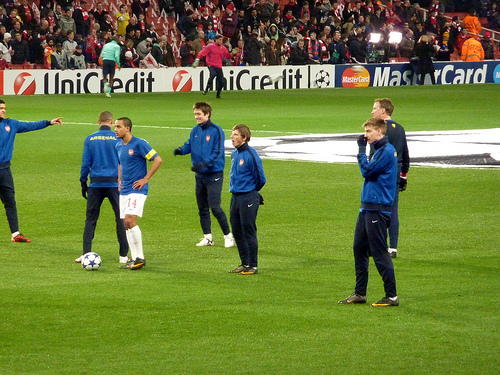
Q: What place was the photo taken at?
A: It was taken at the field.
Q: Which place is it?
A: It is a field.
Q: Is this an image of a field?
A: Yes, it is showing a field.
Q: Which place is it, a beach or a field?
A: It is a field.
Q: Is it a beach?
A: No, it is a field.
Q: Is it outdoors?
A: Yes, it is outdoors.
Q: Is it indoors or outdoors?
A: It is outdoors.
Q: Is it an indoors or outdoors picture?
A: It is outdoors.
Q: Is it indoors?
A: No, it is outdoors.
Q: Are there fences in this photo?
A: No, there are no fences.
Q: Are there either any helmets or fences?
A: No, there are no fences or helmets.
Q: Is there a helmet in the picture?
A: No, there are no helmets.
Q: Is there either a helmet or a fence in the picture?
A: No, there are no helmets or fences.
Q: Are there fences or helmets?
A: No, there are no helmets or fences.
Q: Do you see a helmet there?
A: No, there are no helmets.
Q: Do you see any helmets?
A: No, there are no helmets.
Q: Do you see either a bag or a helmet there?
A: No, there are no helmets or bags.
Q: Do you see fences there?
A: No, there are no fences.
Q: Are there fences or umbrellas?
A: No, there are no fences or umbrellas.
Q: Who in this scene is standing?
A: The people are standing.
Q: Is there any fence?
A: No, there are no fences.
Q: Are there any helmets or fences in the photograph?
A: No, there are no fences or helmets.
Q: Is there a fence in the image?
A: No, there are no fences.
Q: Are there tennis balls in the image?
A: No, there are no tennis balls.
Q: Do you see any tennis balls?
A: No, there are no tennis balls.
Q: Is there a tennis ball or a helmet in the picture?
A: No, there are no tennis balls or helmets.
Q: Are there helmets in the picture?
A: No, there are no helmets.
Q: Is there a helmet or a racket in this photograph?
A: No, there are no helmets or rackets.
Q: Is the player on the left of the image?
A: Yes, the player is on the left of the image.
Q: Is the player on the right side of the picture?
A: No, the player is on the left of the image.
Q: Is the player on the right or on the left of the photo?
A: The player is on the left of the image.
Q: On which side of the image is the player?
A: The player is on the left of the image.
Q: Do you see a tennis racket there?
A: No, there are no rackets.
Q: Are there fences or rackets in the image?
A: No, there are no rackets or fences.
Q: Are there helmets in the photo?
A: No, there are no helmets.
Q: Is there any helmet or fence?
A: No, there are no helmets or fences.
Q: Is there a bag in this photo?
A: No, there are no bags.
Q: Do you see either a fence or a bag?
A: No, there are no bags or fences.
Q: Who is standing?
A: The people are standing.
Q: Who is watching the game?
A: The crowd is watching the game.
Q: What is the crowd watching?
A: The crowd is watching the game.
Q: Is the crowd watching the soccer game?
A: Yes, the crowd is watching the game.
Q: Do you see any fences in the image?
A: No, there are no fences.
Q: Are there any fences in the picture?
A: No, there are no fences.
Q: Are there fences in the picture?
A: No, there are no fences.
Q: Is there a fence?
A: No, there are no fences.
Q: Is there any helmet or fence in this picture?
A: No, there are no fences or helmets.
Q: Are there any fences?
A: No, there are no fences.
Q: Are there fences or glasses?
A: No, there are no fences or glasses.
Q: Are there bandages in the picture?
A: No, there are no bandages.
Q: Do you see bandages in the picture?
A: No, there are no bandages.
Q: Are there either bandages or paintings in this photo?
A: No, there are no bandages or paintings.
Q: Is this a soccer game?
A: Yes, this is a soccer game.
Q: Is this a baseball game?
A: No, this is a soccer game.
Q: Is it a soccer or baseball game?
A: This is a soccer game.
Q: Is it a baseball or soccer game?
A: This is a soccer game.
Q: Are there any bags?
A: No, there are no bags.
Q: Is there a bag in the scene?
A: No, there are no bags.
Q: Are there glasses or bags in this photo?
A: No, there are no bags or glasses.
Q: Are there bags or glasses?
A: No, there are no bags or glasses.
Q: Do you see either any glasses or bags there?
A: No, there are no bags or glasses.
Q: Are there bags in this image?
A: No, there are no bags.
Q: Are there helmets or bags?
A: No, there are no bags or helmets.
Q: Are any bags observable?
A: No, there are no bags.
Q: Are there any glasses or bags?
A: No, there are no bags or glasses.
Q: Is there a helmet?
A: No, there are no helmets.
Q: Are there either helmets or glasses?
A: No, there are no helmets or glasses.